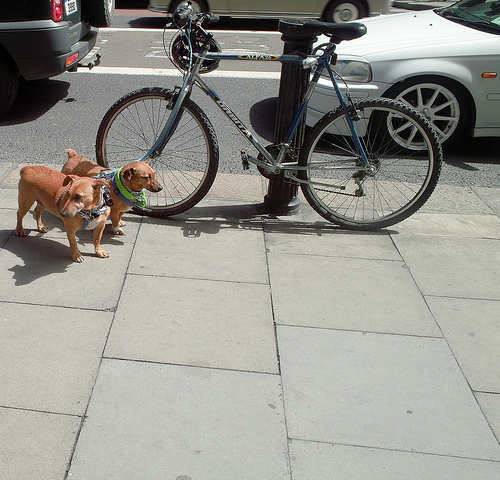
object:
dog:
[14, 166, 111, 264]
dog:
[63, 148, 162, 236]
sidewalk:
[0, 162, 499, 479]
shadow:
[1, 228, 98, 286]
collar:
[111, 167, 147, 207]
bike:
[93, 3, 441, 232]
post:
[264, 17, 322, 214]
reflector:
[481, 72, 497, 79]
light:
[66, 52, 79, 66]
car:
[0, 0, 114, 116]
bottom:
[1, 28, 98, 94]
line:
[77, 65, 299, 79]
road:
[0, 16, 500, 163]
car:
[305, 0, 499, 155]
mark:
[405, 408, 415, 415]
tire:
[373, 76, 470, 156]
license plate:
[62, 1, 77, 15]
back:
[48, 0, 114, 74]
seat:
[302, 20, 366, 43]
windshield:
[434, 0, 499, 37]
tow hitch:
[68, 53, 102, 72]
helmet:
[172, 31, 221, 74]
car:
[146, 1, 393, 29]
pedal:
[239, 148, 281, 175]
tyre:
[94, 86, 220, 219]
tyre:
[299, 97, 443, 232]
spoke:
[142, 99, 154, 133]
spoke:
[170, 143, 206, 154]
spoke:
[161, 167, 168, 206]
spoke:
[319, 138, 364, 159]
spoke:
[370, 177, 377, 222]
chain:
[257, 144, 379, 198]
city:
[1, 2, 499, 476]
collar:
[77, 185, 111, 220]